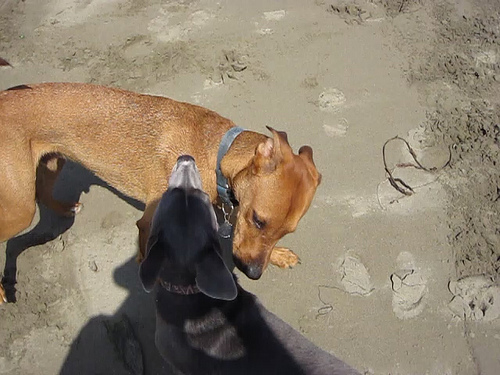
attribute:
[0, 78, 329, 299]
dog — playing, brown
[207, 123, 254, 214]
collar — blue, grey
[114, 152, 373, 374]
dog — standing, black, grey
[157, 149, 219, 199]
snout — white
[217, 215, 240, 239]
tag — silver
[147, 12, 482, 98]
sand — grey